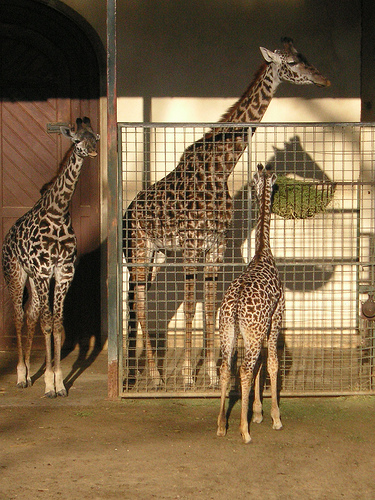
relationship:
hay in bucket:
[279, 172, 319, 204] [271, 176, 338, 219]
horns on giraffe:
[70, 111, 100, 133] [5, 116, 107, 403]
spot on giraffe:
[42, 242, 56, 253] [5, 116, 107, 403]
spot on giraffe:
[261, 85, 278, 103] [93, 35, 333, 378]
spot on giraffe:
[243, 296, 257, 311] [207, 165, 302, 446]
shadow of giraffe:
[273, 136, 331, 187] [93, 35, 333, 378]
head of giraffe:
[257, 34, 337, 92] [93, 35, 333, 378]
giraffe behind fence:
[93, 35, 333, 378] [126, 125, 222, 398]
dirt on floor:
[28, 411, 121, 500] [74, 356, 108, 410]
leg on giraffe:
[268, 333, 287, 431] [207, 165, 302, 446]